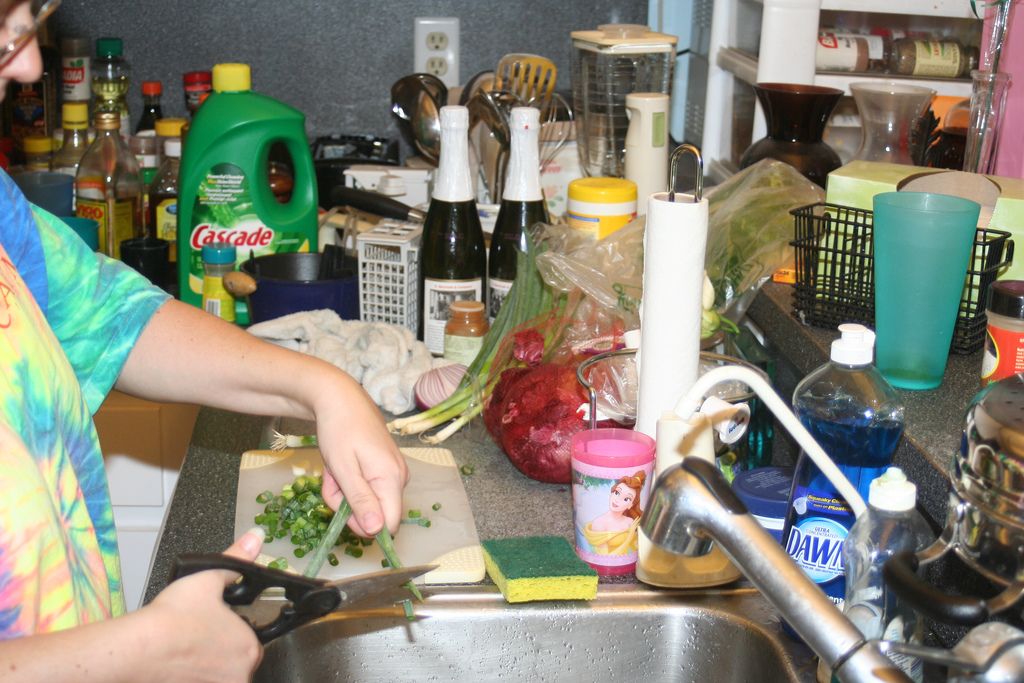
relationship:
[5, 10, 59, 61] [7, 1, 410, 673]
glasses worn by human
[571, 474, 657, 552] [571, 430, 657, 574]
carton on cup